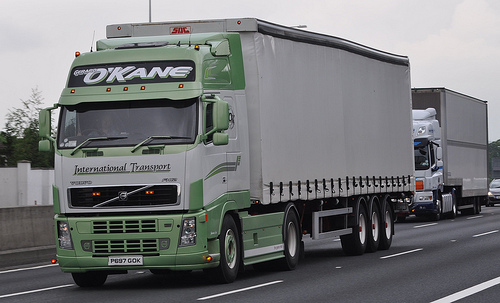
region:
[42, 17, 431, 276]
semi truck driving down the road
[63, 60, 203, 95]
white letters on black back ground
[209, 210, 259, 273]
tire with silver rim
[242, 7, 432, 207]
white semi trailer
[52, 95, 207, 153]
windshield of semi truck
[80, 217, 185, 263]
grill front of truck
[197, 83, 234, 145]
green side mirror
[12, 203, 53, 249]
grey barrier wall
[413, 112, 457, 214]
white semi truck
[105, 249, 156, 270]
white license plate with black letters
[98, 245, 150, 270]
license plate has black writing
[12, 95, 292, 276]
truck is white and green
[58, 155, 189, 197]
international transport written in black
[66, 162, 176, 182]
international transport written in black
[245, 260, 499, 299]
street is grey concrete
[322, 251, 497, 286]
street is grey concrete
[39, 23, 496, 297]
trucks on the road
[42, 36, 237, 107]
green trim on truck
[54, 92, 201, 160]
windshield on the truck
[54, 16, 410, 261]
green and white cargo truck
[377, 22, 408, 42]
white clouds in blue sky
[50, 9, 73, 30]
white clouds in blue sky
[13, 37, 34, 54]
white clouds in blue sky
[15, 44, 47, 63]
white clouds in blue sky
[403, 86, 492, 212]
a large white truck